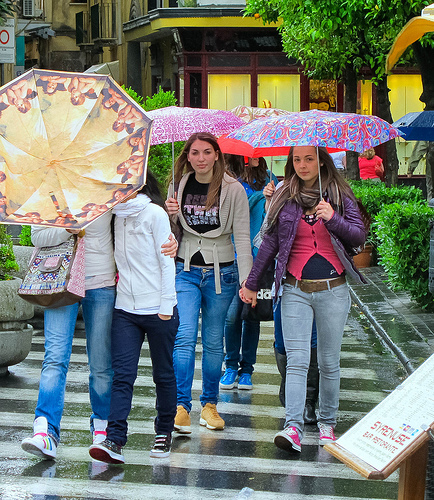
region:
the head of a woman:
[155, 130, 235, 185]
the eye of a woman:
[177, 122, 229, 178]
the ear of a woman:
[208, 130, 235, 164]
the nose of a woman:
[191, 150, 212, 168]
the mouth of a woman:
[190, 150, 230, 180]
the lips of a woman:
[186, 155, 220, 181]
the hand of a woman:
[155, 188, 186, 227]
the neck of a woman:
[183, 157, 221, 199]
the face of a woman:
[181, 132, 225, 185]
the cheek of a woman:
[183, 143, 204, 175]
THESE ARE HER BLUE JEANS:
[39, 286, 116, 431]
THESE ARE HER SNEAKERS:
[88, 432, 173, 464]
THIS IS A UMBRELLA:
[1, 66, 154, 230]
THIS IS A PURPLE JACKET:
[244, 181, 371, 291]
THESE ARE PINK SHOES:
[272, 423, 345, 454]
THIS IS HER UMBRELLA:
[207, 106, 399, 153]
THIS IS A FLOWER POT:
[0, 231, 35, 384]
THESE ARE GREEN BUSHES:
[345, 178, 432, 315]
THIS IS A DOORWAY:
[207, 69, 307, 176]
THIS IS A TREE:
[243, 3, 430, 89]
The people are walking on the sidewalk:
[5, 61, 432, 497]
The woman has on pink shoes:
[271, 419, 344, 458]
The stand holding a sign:
[324, 351, 431, 497]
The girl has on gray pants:
[273, 281, 353, 434]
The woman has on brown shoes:
[168, 398, 228, 435]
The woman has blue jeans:
[168, 258, 238, 408]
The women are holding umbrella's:
[141, 104, 405, 165]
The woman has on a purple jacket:
[242, 183, 370, 296]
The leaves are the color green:
[242, 2, 421, 85]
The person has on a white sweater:
[110, 198, 182, 317]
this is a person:
[246, 128, 365, 469]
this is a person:
[167, 142, 260, 439]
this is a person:
[224, 145, 284, 395]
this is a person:
[355, 135, 391, 191]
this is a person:
[85, 202, 178, 468]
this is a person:
[25, 221, 129, 475]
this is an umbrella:
[2, 73, 161, 231]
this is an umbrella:
[147, 97, 250, 149]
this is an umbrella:
[227, 113, 383, 170]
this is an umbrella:
[216, 101, 300, 142]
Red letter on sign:
[371, 420, 380, 431]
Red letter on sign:
[376, 421, 384, 433]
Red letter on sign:
[379, 424, 388, 435]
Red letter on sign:
[381, 426, 390, 436]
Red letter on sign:
[385, 430, 396, 440]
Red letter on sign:
[391, 429, 400, 440]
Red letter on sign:
[391, 434, 403, 444]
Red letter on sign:
[397, 436, 411, 449]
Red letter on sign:
[390, 445, 400, 456]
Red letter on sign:
[385, 441, 396, 452]